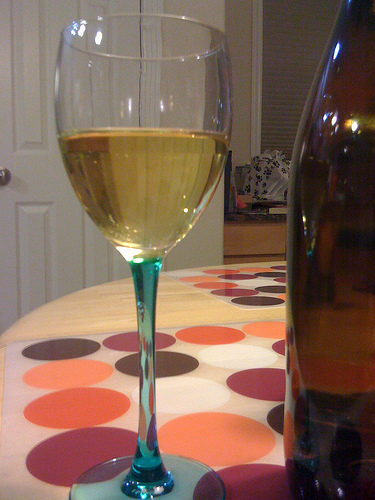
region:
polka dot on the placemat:
[244, 364, 284, 398]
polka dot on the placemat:
[143, 369, 225, 411]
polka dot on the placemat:
[45, 389, 118, 426]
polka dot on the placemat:
[38, 354, 109, 388]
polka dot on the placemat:
[32, 334, 92, 363]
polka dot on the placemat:
[116, 356, 180, 377]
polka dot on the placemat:
[183, 325, 237, 339]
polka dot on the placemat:
[249, 319, 283, 340]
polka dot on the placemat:
[193, 336, 256, 370]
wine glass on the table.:
[50, 11, 232, 497]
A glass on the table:
[46, 6, 230, 498]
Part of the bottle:
[345, 227, 367, 302]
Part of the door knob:
[1, 169, 6, 178]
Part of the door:
[35, 206, 52, 256]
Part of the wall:
[205, 2, 219, 14]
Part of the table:
[83, 302, 104, 320]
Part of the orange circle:
[208, 422, 225, 445]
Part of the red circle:
[72, 446, 95, 454]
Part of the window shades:
[265, 39, 287, 66]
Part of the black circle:
[53, 345, 68, 354]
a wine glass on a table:
[52, 25, 232, 455]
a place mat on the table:
[8, 330, 300, 495]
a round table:
[2, 273, 325, 496]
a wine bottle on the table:
[290, 5, 371, 487]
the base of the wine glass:
[72, 449, 204, 498]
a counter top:
[227, 177, 289, 220]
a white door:
[2, 6, 143, 303]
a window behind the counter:
[262, 6, 318, 172]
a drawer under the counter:
[225, 219, 295, 258]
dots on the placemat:
[27, 337, 282, 493]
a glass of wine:
[29, 7, 264, 493]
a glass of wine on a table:
[28, 8, 283, 488]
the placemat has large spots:
[0, 302, 331, 492]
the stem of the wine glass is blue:
[82, 257, 259, 497]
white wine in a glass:
[33, 97, 255, 280]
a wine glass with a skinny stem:
[30, 11, 285, 495]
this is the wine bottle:
[258, 20, 373, 498]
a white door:
[1, 1, 175, 355]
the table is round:
[8, 244, 326, 495]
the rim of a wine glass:
[37, 12, 256, 75]